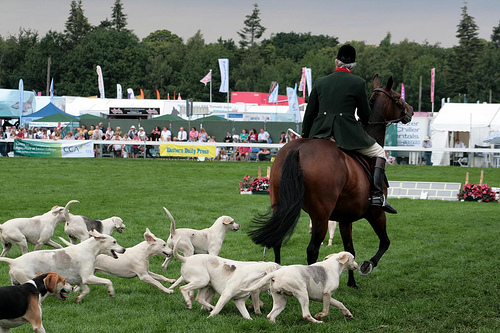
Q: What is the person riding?
A: Horse.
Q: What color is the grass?
A: Green.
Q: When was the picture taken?
A: Daytime.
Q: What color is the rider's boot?
A: Black.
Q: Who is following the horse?
A: Dogs.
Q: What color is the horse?
A: Brown.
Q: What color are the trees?
A: Green.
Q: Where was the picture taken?
A: At a equestrian track.